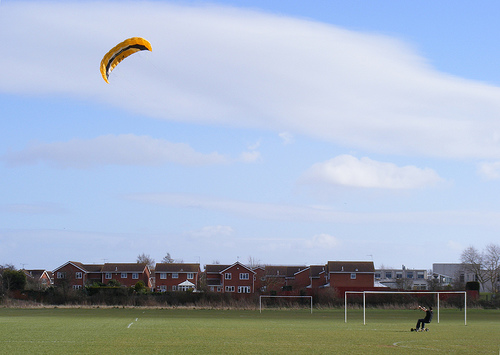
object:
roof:
[18, 269, 51, 285]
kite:
[100, 36, 153, 85]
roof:
[326, 261, 375, 275]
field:
[1, 306, 498, 354]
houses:
[0, 261, 499, 301]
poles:
[343, 291, 467, 326]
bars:
[344, 291, 467, 326]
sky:
[0, 1, 500, 271]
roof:
[50, 261, 90, 274]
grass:
[1, 308, 498, 354]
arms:
[416, 305, 425, 312]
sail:
[98, 36, 153, 85]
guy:
[409, 303, 437, 335]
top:
[424, 311, 434, 323]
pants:
[416, 318, 431, 330]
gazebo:
[177, 279, 196, 292]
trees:
[0, 263, 31, 295]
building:
[51, 260, 378, 295]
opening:
[467, 281, 480, 291]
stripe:
[106, 44, 148, 76]